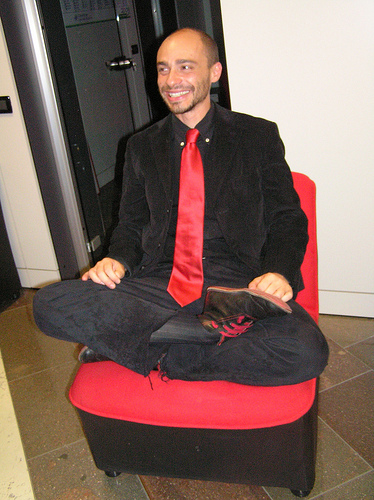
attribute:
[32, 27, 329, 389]
man — smiling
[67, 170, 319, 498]
chair — red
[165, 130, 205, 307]
tie — red, long, stylish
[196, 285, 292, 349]
shoe — black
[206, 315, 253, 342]
shoelaces — red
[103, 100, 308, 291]
jacket — black, stylish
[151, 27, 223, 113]
head — bald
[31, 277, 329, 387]
legs — crossed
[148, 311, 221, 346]
sock — black, pin striped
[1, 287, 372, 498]
floor — tiled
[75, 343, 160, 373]
shoe — black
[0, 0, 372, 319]
wall — white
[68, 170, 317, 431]
cushion — red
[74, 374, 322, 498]
base — black, supportive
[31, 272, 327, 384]
pants — black